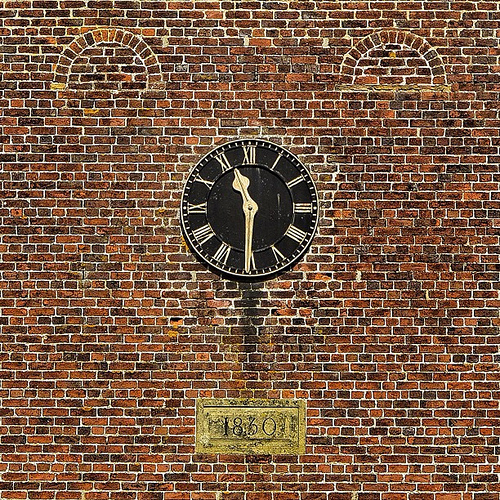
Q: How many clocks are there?
A: One.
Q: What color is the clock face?
A: Black.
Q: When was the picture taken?
A: Daytime.